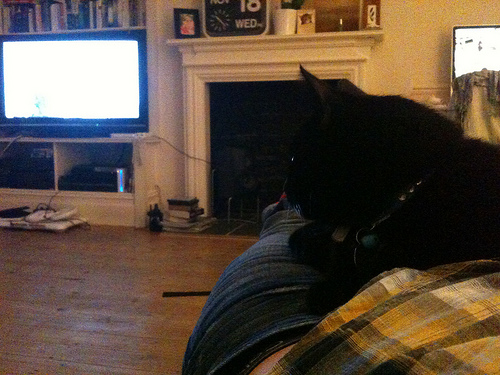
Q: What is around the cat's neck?
A: Collar with a bell.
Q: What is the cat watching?
A: Tv.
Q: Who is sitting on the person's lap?
A: A cat.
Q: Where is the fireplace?
A: Against the wall.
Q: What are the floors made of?
A: Wood.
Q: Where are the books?
A: On the bookshelf on the left.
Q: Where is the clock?
A: On the mantle.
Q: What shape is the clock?
A: Square.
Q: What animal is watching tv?
A: Cat.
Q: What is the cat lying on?
A: A person wearing jeans.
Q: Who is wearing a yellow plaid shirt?
A: The person holding the cat.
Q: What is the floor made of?
A: Wood.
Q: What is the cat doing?
A: Lying on a person.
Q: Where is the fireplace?
A: In the living room.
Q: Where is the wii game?
A: Below the big screen tv.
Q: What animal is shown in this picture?
A: A cat.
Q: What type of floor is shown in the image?
A: Brown wooden floor.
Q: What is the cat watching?
A: Television.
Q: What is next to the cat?
A: A patterned cloth.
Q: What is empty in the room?
A: A fireplace.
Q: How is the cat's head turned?
A: Towards the tv.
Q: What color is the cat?
A: Black.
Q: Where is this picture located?
A: Living room.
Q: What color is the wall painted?
A: White.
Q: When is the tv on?
A: Now.